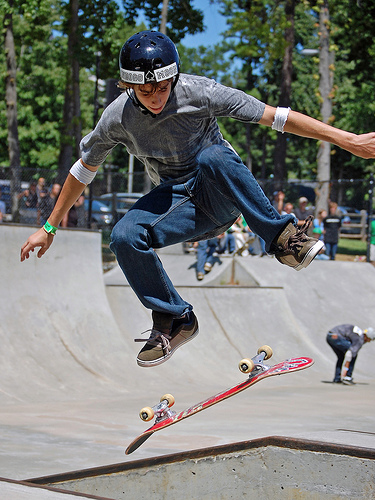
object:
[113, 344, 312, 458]
skateboard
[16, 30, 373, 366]
boy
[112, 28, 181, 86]
helmet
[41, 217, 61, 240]
wristband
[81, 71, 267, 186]
shirt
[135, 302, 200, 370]
shoes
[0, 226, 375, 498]
ramp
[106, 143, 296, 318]
pants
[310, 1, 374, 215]
trees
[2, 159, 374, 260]
fence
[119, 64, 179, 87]
trim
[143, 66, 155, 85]
spade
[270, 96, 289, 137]
band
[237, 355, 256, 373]
skateboard's wheels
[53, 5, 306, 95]
sky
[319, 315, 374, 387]
person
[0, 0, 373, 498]
background